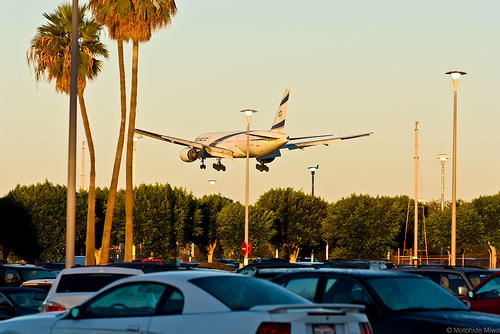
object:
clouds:
[0, 0, 500, 200]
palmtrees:
[88, 0, 178, 264]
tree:
[0, 178, 83, 262]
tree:
[103, 180, 204, 259]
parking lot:
[0, 261, 500, 334]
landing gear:
[255, 164, 269, 172]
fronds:
[41, 12, 61, 26]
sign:
[242, 241, 251, 256]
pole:
[240, 108, 258, 267]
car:
[270, 267, 500, 334]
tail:
[270, 89, 290, 134]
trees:
[459, 190, 500, 269]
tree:
[217, 201, 274, 259]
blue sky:
[247, 17, 476, 55]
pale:
[285, 48, 315, 73]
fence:
[401, 258, 488, 266]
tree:
[418, 207, 485, 266]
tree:
[194, 191, 232, 263]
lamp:
[445, 70, 467, 266]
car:
[38, 266, 145, 314]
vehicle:
[0, 270, 374, 334]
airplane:
[133, 88, 374, 172]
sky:
[0, 0, 500, 204]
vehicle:
[320, 259, 397, 270]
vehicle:
[383, 265, 499, 300]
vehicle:
[0, 286, 43, 321]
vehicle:
[0, 263, 57, 287]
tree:
[320, 192, 401, 260]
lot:
[7, 242, 490, 330]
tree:
[25, 1, 110, 266]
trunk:
[81, 111, 95, 241]